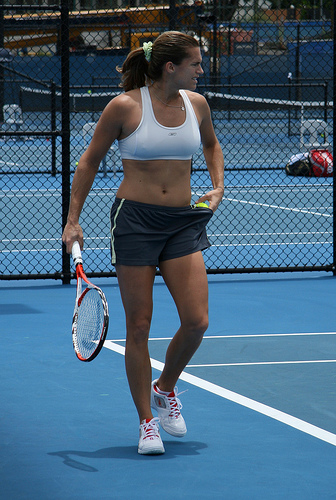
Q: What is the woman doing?
A: Walking.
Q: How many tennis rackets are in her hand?
A: One.